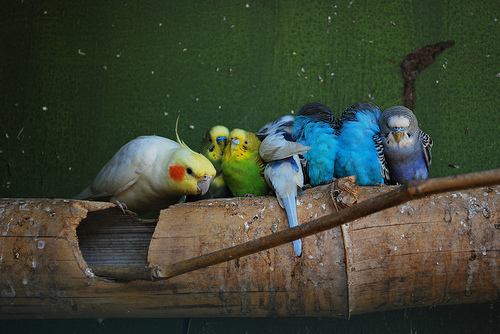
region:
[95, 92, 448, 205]
the birds are colorful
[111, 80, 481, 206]
the birds are colorful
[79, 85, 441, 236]
the birds are colorful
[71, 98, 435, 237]
the birds are colorful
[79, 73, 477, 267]
the birds are colorful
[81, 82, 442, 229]
the birds are colorful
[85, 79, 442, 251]
the birds are colorful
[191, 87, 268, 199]
Yellow and green bird on a branch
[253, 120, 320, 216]
Blue bird on a branch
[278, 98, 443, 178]
Several blue birds on a branch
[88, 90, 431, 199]
Birds sitting together on a branch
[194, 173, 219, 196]
Beak on a bird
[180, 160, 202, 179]
Eye on a bird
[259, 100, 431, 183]
Four birds have blue feathers.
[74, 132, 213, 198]
The large bird is on the left.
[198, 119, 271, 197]
Two birds are yellow and green.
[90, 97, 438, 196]
Eight birds are sitting on a log.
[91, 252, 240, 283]
A twig is sticking out of a hole.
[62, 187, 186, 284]
A hole is in the log.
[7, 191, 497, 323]
The log appears to be wood.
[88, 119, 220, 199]
The large bird is looking down.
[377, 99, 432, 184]
The bird on the end is looking down.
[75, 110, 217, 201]
white cockatiel with yellow head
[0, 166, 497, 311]
hollow wooden perch below birds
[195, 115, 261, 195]
pair of green and yellow lovebirds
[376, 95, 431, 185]
fluffy bird with blue body and gray head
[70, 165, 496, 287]
long crack in hollow perch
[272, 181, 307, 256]
long blue tail feather badly photoshopped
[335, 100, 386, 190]
bright blue bird with head tucked in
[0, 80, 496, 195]
dark green fabric behind birds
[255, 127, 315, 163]
on pale blue wing stretched out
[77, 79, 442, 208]
birds on a log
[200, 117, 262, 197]
green and yellow birds huddled together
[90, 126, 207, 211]
larger white bird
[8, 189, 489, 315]
large log with small stick in it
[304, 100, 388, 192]
two similar blue birds together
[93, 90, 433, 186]
group of 7 birds perched together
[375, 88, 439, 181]
white grey and blue bird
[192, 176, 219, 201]
beak of white bird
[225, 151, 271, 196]
wide green chest of small bird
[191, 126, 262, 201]
two green birds huddle closely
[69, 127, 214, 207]
white bird with yellow head and red spot on its cheek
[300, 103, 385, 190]
two bright blue birds with black and white striped wings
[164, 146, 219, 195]
a bird with orange feathers on its head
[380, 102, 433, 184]
a blue grey and black bird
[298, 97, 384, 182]
two birds with blue feathers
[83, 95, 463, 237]
seven birds in a row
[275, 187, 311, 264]
a brid's blue tail feather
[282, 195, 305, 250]
blue tail of the bird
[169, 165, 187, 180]
orange spot on the bird's cheek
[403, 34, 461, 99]
brown spot on the green wall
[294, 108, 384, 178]
two blue birds with their back's facing the camera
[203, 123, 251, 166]
two parakeets facing the camera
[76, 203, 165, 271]
hole in the wood branch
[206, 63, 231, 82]
white spot on the green wall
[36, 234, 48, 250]
white spot on the branch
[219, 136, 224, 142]
blue spot above the beak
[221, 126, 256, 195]
a bird on the log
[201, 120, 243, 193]
a bird on the log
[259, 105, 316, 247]
a bird on the log